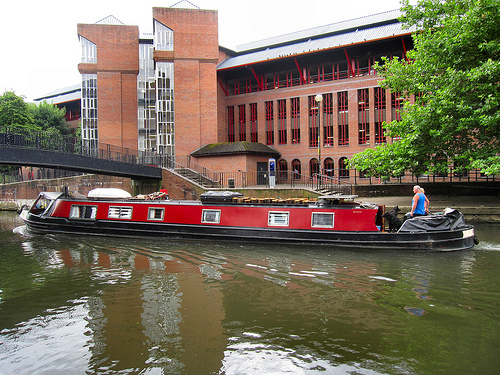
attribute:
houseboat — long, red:
[18, 183, 478, 251]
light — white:
[309, 90, 326, 105]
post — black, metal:
[309, 98, 328, 192]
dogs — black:
[363, 154, 420, 235]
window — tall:
[337, 89, 349, 149]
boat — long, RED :
[28, 187, 491, 254]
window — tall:
[235, 99, 244, 142]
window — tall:
[336, 90, 347, 145]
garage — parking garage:
[33, 0, 497, 196]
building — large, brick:
[28, 0, 499, 188]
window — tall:
[258, 96, 276, 148]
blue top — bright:
[408, 192, 427, 217]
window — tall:
[246, 101, 260, 146]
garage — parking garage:
[75, 7, 489, 188]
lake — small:
[5, 225, 499, 372]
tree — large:
[338, 2, 497, 185]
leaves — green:
[337, 142, 421, 177]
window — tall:
[320, 89, 335, 151]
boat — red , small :
[13, 179, 479, 256]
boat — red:
[131, 170, 355, 244]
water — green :
[0, 210, 499, 373]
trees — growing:
[403, 10, 493, 169]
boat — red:
[21, 182, 481, 249]